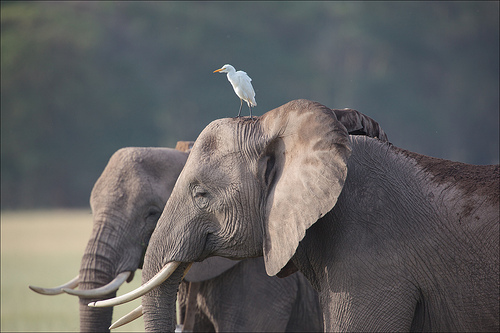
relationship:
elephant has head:
[28, 141, 325, 332] [143, 100, 262, 262]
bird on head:
[212, 61, 259, 121] [143, 100, 262, 262]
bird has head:
[212, 61, 259, 121] [216, 63, 234, 73]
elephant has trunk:
[28, 141, 325, 332] [86, 262, 177, 311]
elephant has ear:
[28, 141, 325, 332] [263, 98, 354, 278]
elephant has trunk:
[28, 141, 325, 332] [79, 213, 124, 332]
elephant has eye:
[28, 141, 325, 332] [191, 185, 210, 202]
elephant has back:
[28, 141, 325, 332] [349, 132, 499, 332]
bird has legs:
[212, 61, 259, 121] [234, 97, 254, 119]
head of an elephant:
[178, 84, 358, 292] [148, 65, 498, 324]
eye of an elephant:
[186, 178, 223, 205] [167, 114, 442, 327]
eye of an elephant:
[134, 204, 162, 226] [64, 126, 202, 311]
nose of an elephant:
[66, 226, 120, 322] [73, 126, 185, 321]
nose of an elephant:
[126, 251, 196, 324] [135, 99, 485, 329]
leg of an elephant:
[313, 272, 417, 329] [193, 104, 491, 324]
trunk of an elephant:
[124, 230, 199, 325] [135, 99, 485, 329]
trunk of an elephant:
[107, 300, 164, 329] [135, 99, 485, 329]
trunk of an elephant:
[51, 273, 151, 313] [47, 137, 198, 329]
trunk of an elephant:
[23, 261, 82, 308] [26, 137, 209, 325]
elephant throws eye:
[135, 99, 485, 329] [193, 190, 210, 198]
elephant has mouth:
[28, 141, 325, 332] [194, 227, 212, 261]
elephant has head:
[28, 146, 298, 332] [28, 146, 190, 331]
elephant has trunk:
[28, 146, 298, 332] [77, 213, 129, 332]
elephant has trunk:
[28, 141, 325, 332] [141, 217, 192, 331]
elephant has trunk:
[28, 141, 325, 332] [140, 212, 178, 331]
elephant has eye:
[28, 141, 325, 332] [190, 180, 210, 200]